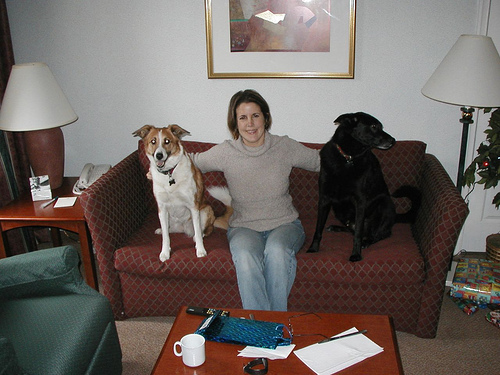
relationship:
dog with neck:
[306, 112, 423, 263] [333, 137, 372, 168]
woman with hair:
[188, 90, 322, 311] [227, 90, 272, 141]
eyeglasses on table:
[287, 310, 332, 340] [150, 304, 405, 374]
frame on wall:
[204, 0, 358, 80] [4, 0, 484, 186]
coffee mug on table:
[174, 333, 207, 366] [150, 304, 405, 374]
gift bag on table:
[195, 309, 293, 349] [150, 304, 405, 374]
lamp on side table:
[1, 62, 79, 192] [1, 176, 100, 292]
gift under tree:
[450, 255, 500, 305] [461, 107, 499, 209]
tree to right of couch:
[461, 107, 499, 209] [79, 139, 470, 337]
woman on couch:
[188, 90, 322, 311] [79, 139, 470, 337]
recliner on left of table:
[1, 244, 123, 374] [150, 304, 405, 374]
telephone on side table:
[73, 163, 112, 195] [1, 176, 100, 292]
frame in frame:
[204, 0, 358, 80] [204, 1, 358, 80]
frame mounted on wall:
[204, 1, 358, 80] [4, 0, 484, 186]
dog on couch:
[306, 112, 423, 263] [79, 139, 470, 337]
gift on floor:
[450, 255, 500, 305] [80, 254, 499, 374]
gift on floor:
[447, 290, 480, 316] [80, 254, 499, 374]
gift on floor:
[485, 309, 500, 328] [80, 254, 499, 374]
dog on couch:
[132, 125, 226, 262] [79, 139, 470, 337]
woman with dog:
[188, 90, 322, 311] [306, 112, 423, 263]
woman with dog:
[188, 90, 322, 311] [132, 125, 226, 262]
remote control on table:
[185, 304, 230, 320] [150, 304, 405, 374]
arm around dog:
[185, 141, 228, 173] [132, 125, 226, 262]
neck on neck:
[333, 137, 372, 168] [332, 137, 371, 162]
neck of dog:
[332, 137, 371, 162] [306, 112, 423, 263]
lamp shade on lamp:
[0, 63, 79, 131] [1, 62, 79, 192]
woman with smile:
[188, 90, 322, 311] [244, 128, 257, 135]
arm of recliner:
[0, 245, 82, 298] [1, 244, 123, 374]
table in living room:
[150, 304, 405, 374] [1, 1, 499, 373]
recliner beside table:
[1, 244, 123, 374] [150, 304, 405, 374]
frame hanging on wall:
[204, 0, 358, 80] [4, 0, 484, 186]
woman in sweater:
[188, 90, 322, 311] [188, 130, 322, 232]